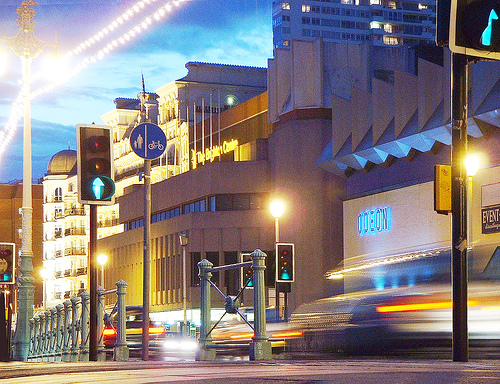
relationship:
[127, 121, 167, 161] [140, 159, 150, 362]
sign on pole